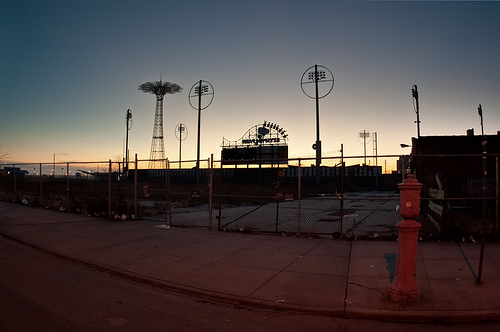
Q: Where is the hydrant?
A: Sidewalk.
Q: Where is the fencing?
A: Along the sidewalk.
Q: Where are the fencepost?
A: Under fencing.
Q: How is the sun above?
A: Setting.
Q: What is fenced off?
A: A amusement park.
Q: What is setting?
A: Sun.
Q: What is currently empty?
A: The sidewalk.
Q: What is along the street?
A: A curb.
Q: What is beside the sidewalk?
A: A curb.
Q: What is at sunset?
A: The horizon.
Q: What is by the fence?
A: A sidewalk.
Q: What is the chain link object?
A: Fence.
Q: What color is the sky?
A: Blue.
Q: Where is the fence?
A: On the ground.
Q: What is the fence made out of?
A: Metal.